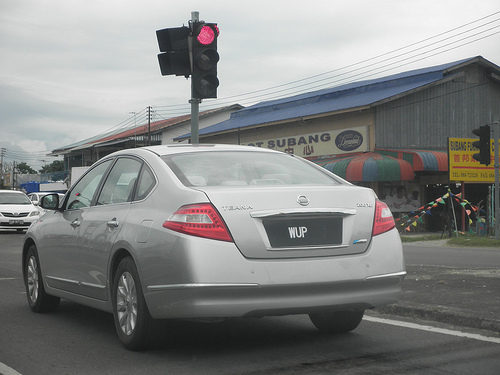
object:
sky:
[0, 0, 499, 176]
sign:
[446, 138, 499, 183]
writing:
[239, 119, 379, 167]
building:
[172, 55, 500, 234]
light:
[162, 203, 234, 243]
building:
[46, 103, 247, 189]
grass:
[399, 234, 500, 244]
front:
[374, 54, 500, 235]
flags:
[395, 189, 482, 237]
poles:
[462, 181, 465, 234]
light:
[370, 199, 395, 237]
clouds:
[0, 0, 113, 102]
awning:
[374, 147, 449, 171]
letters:
[287, 226, 307, 239]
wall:
[375, 62, 500, 151]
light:
[156, 11, 189, 99]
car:
[22, 143, 405, 351]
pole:
[189, 12, 199, 144]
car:
[28, 192, 65, 217]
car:
[0, 189, 39, 232]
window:
[160, 151, 341, 187]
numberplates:
[262, 217, 343, 248]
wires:
[202, 11, 500, 112]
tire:
[111, 255, 166, 350]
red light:
[197, 25, 214, 45]